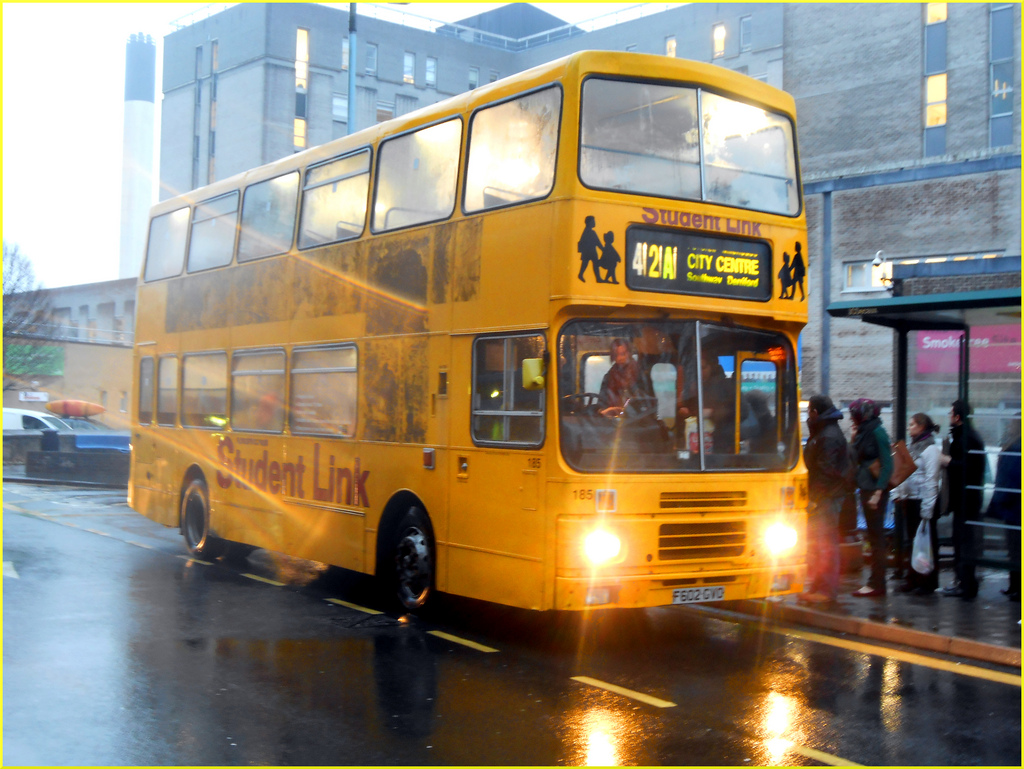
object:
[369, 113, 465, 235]
window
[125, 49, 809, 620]
bus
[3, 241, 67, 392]
leaves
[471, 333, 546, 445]
window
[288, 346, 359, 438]
window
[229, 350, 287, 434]
window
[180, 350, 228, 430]
window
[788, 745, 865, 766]
line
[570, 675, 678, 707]
line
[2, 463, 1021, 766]
road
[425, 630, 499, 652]
line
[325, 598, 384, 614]
line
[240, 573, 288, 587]
line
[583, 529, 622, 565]
right light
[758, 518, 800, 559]
left headlight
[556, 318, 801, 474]
driver's window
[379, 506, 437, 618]
wheel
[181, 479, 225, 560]
wheel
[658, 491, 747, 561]
grate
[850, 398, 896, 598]
person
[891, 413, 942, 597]
person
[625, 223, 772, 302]
lcd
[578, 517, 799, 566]
lights